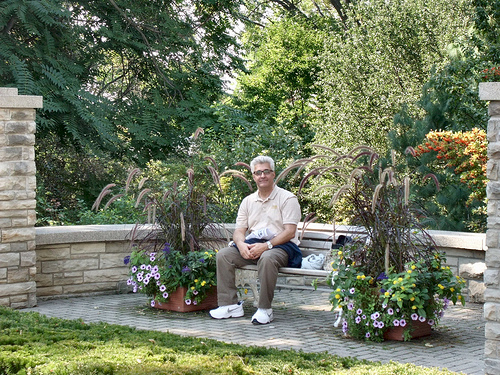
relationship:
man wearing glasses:
[205, 154, 303, 326] [253, 167, 268, 177]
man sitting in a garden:
[207, 154, 303, 327] [20, 104, 490, 373]